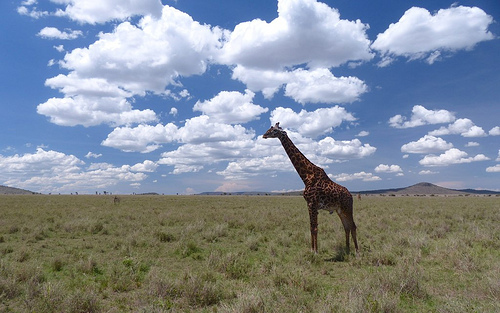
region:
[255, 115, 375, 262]
this is a giraffe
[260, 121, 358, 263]
the giraffe is tall in size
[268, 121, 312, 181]
the giraffe has long neck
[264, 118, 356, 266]
the giraffe is brown and white in color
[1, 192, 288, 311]
the grass are long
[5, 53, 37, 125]
the sky is blue in color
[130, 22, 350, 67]
the clouds are white in color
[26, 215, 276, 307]
the grass is brown in color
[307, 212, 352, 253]
the giraffe has long neck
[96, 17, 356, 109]
the clouds are cotton like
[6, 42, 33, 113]
this is the sky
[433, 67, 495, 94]
the sky is blue in color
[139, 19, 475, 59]
the sky has many clouds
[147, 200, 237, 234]
the grass is green in color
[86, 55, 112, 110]
the clouds are white in color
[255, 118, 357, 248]
the giraffe is tall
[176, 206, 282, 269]
this is the grass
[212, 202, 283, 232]
the grass is green in color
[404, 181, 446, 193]
this is a hill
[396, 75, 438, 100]
part of the sky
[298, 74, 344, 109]
part of a white cloud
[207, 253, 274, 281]
part of green grass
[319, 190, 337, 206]
stomach of a giraffe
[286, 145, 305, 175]
neck of a giraffe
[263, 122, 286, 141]
head of a giraffe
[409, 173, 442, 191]
part of a hill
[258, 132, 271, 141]
part of the giraffe's mouth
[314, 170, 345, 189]
back of a giraffe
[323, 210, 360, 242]
hind legs of the giraffe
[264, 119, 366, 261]
The giraffe in the photo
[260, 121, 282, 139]
The head of the giraffe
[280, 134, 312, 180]
The neck of the giraffe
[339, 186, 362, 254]
The giraffe's hind legs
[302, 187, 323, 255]
The front legs of the giraffe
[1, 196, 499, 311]
The grass field the giraffe is on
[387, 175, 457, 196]
The hill that is fully visible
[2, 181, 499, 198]
The horizon line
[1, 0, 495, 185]
The clouds in the sky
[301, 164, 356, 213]
The body of the giraffe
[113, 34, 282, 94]
thick white clouds floating in the sky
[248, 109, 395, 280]
a giraffe standing alone in field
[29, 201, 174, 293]
dead grass dotting the ground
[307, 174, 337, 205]
brown spots on the giraffe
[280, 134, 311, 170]
a really long neck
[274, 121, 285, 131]
horns on top of a head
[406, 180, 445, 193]
a small mountain in the distance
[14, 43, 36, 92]
a clear blue color in the sk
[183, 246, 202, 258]
a clump of green grass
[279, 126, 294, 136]
a ear on a head